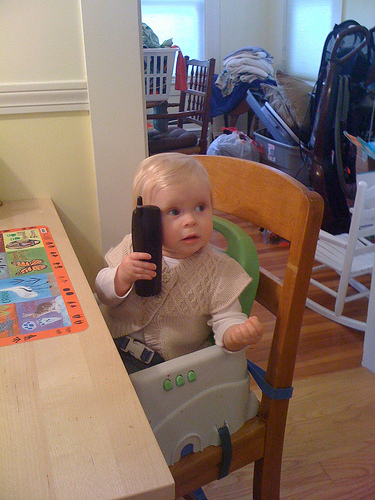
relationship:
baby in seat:
[94, 152, 259, 351] [125, 341, 273, 465]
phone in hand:
[126, 201, 163, 304] [118, 252, 157, 284]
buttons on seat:
[153, 361, 205, 397] [125, 341, 273, 465]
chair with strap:
[143, 171, 296, 499] [252, 363, 296, 405]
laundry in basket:
[128, 16, 172, 51] [127, 48, 180, 96]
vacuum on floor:
[308, 22, 374, 222] [252, 246, 372, 462]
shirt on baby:
[98, 232, 263, 351] [94, 152, 259, 351]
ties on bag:
[222, 121, 270, 148] [200, 128, 272, 163]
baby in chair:
[94, 152, 259, 351] [143, 171, 296, 499]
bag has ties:
[200, 128, 272, 163] [222, 121, 270, 148]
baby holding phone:
[94, 152, 259, 351] [126, 201, 163, 304]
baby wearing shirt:
[94, 152, 259, 351] [98, 232, 263, 351]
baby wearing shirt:
[94, 152, 259, 351] [98, 263, 263, 350]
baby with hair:
[94, 152, 259, 351] [134, 155, 211, 184]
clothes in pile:
[220, 43, 278, 87] [224, 47, 273, 87]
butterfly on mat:
[16, 256, 44, 277] [2, 224, 83, 347]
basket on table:
[127, 48, 180, 96] [126, 100, 168, 142]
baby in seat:
[114, 157, 259, 358] [125, 341, 273, 465]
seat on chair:
[125, 341, 273, 465] [143, 171, 296, 499]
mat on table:
[2, 224, 83, 347] [3, 178, 156, 500]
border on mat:
[44, 226, 87, 325] [2, 224, 83, 347]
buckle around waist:
[125, 328, 155, 372] [104, 327, 169, 367]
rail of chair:
[323, 28, 354, 167] [143, 171, 296, 499]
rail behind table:
[323, 28, 354, 167] [3, 178, 156, 500]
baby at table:
[114, 157, 259, 358] [3, 178, 156, 500]